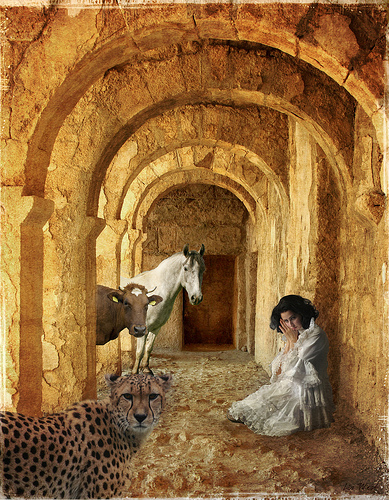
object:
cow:
[93, 281, 164, 347]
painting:
[0, 2, 385, 498]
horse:
[120, 242, 206, 375]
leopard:
[6, 367, 170, 500]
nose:
[133, 412, 148, 424]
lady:
[222, 292, 332, 440]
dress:
[227, 317, 330, 439]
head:
[177, 242, 207, 306]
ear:
[97, 369, 122, 389]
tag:
[149, 299, 157, 307]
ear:
[106, 290, 124, 307]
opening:
[180, 252, 242, 353]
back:
[143, 228, 245, 351]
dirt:
[148, 436, 364, 499]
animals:
[0, 240, 211, 499]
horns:
[118, 281, 159, 293]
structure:
[1, 0, 385, 446]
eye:
[120, 391, 134, 403]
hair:
[270, 294, 320, 335]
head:
[268, 293, 323, 335]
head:
[101, 364, 175, 435]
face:
[280, 310, 299, 331]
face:
[123, 296, 148, 331]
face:
[182, 261, 205, 298]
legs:
[128, 333, 155, 375]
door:
[178, 251, 241, 352]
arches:
[0, 0, 389, 456]